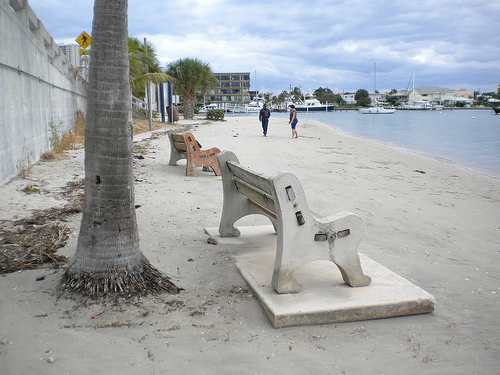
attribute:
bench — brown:
[167, 129, 219, 176]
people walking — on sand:
[254, 102, 300, 138]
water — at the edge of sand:
[361, 135, 422, 159]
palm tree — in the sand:
[72, 3, 156, 296]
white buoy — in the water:
[468, 111, 478, 119]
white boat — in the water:
[359, 102, 397, 114]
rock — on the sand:
[44, 352, 60, 362]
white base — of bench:
[206, 221, 438, 328]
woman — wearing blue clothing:
[286, 100, 299, 139]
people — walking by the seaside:
[256, 100, 301, 139]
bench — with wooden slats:
[161, 130, 224, 176]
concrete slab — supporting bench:
[204, 219, 436, 328]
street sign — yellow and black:
[75, 29, 93, 48]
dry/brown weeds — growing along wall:
[46, 114, 89, 152]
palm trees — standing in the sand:
[163, 57, 213, 119]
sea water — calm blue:
[394, 113, 471, 148]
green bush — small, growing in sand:
[207, 105, 224, 122]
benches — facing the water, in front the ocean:
[166, 127, 375, 296]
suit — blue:
[286, 109, 298, 124]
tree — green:
[169, 54, 217, 124]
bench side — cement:
[272, 171, 369, 291]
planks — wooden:
[230, 161, 278, 215]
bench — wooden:
[167, 127, 223, 173]